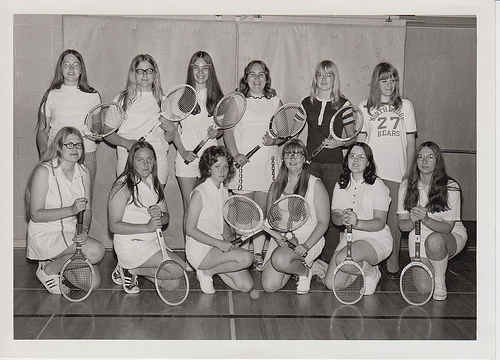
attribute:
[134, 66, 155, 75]
glasses — black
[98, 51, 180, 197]
girl — blonde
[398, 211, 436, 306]
tennis rackets — Held 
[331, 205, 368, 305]
tennis rackets — Held 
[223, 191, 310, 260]
tennis rackets — Held 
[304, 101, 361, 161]
tennis rackets — Held 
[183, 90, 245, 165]
tennis rackets — Held 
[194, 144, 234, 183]
hair — short, curly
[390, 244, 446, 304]
racket — white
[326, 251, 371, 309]
racket — white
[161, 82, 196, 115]
racket — white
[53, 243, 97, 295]
racket — white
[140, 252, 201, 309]
racket — white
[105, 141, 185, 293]
female — White 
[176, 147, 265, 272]
player — White 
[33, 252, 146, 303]
shoes — striped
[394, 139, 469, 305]
female — Smiling 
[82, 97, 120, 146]
racket — Held 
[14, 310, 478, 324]
stripe — black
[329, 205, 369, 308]
tennis racket — Black, White 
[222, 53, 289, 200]
tennis player — White 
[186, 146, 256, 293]
female — Smiling 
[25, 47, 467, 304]
tennis team — all girls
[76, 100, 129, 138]
racket — Black , White 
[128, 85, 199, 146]
racket — Black , White 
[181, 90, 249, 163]
racket — Black , White 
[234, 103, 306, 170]
racket — Black , White 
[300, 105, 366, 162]
racket — Black , White 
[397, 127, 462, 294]
woman — dark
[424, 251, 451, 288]
socks — white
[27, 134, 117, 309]
player — White 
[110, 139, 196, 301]
player — White 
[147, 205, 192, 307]
tennis racket — White , Black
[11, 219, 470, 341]
floor — shiny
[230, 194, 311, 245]
tennis racket — Black , White 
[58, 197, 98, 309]
racket — Held 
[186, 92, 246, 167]
tennis racket — White , Black 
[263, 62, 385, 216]
shirt — dark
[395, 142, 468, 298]
tennis player — White 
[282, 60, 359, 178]
player — female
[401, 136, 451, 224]
hair — long